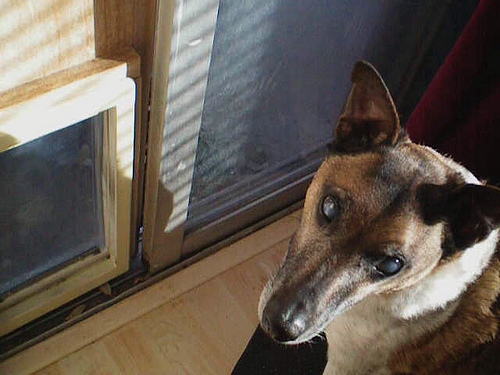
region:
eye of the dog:
[370, 248, 406, 280]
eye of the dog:
[307, 198, 359, 237]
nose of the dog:
[250, 311, 315, 361]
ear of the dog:
[423, 166, 495, 248]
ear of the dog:
[341, 73, 401, 143]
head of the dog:
[257, 73, 461, 355]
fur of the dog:
[419, 308, 441, 332]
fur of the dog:
[363, 312, 411, 354]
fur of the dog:
[424, 330, 454, 357]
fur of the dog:
[353, 325, 380, 355]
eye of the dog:
[373, 258, 412, 288]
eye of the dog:
[311, 190, 328, 242]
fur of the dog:
[436, 241, 473, 287]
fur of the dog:
[388, 299, 412, 316]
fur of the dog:
[386, 162, 408, 188]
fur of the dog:
[455, 333, 485, 366]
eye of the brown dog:
[315, 190, 345, 223]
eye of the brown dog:
[372, 253, 409, 280]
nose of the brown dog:
[254, 297, 317, 345]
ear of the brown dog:
[328, 58, 403, 153]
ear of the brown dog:
[431, 164, 498, 243]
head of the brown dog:
[244, 49, 499, 349]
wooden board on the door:
[137, 0, 227, 273]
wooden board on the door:
[176, 158, 326, 255]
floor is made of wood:
[2, 208, 307, 369]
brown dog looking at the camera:
[236, 55, 497, 374]